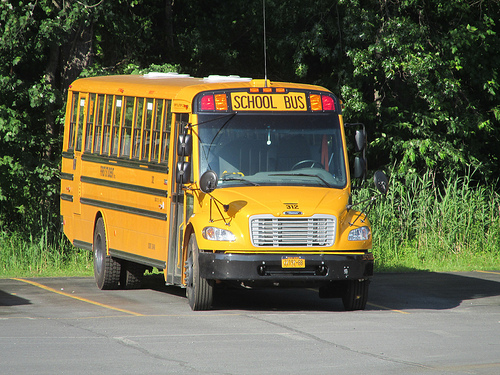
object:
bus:
[58, 70, 374, 312]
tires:
[92, 217, 121, 290]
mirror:
[175, 160, 194, 184]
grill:
[247, 214, 338, 247]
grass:
[3, 157, 499, 277]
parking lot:
[4, 269, 499, 375]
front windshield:
[197, 116, 347, 184]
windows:
[156, 97, 174, 168]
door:
[168, 113, 190, 285]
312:
[285, 202, 299, 210]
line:
[9, 275, 146, 315]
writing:
[99, 163, 115, 179]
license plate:
[279, 257, 309, 270]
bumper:
[202, 254, 369, 284]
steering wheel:
[291, 158, 322, 173]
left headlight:
[348, 225, 371, 243]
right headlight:
[203, 225, 240, 243]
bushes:
[3, 2, 499, 232]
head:
[187, 83, 377, 282]